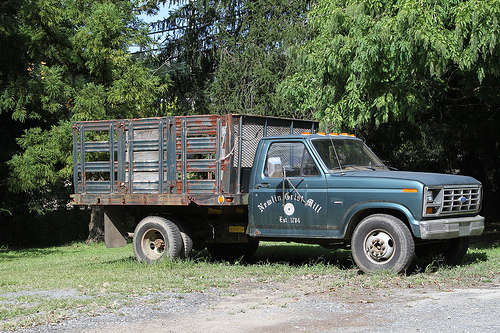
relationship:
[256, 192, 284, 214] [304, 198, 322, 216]
newlin grist mill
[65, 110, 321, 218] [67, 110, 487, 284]
bed of truck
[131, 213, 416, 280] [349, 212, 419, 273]
tires nearly bald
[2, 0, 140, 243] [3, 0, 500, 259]
tree in background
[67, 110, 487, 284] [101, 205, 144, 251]
truck mud flaps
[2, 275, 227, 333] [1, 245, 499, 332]
gravel in foreground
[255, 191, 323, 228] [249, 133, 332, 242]
letters on door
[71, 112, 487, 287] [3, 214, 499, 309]
parked in grass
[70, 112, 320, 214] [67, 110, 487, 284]
back of truck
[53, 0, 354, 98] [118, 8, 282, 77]
covered electrical lines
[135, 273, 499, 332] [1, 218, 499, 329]
dirt covering ground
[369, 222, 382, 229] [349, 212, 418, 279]
black old tire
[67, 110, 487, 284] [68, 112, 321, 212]
truck with trailer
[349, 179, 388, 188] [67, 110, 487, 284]
green pickup truck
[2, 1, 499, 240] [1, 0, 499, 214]
trees with leaves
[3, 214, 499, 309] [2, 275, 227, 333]
grass and gravel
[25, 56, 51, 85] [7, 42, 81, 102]
flowers on branch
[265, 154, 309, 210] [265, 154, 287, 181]
side view mirror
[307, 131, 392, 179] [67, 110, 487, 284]
windshield of truck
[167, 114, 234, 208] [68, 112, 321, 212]
rusty grid trailer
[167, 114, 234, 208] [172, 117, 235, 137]
rusty trailer railing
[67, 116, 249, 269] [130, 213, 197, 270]
rear two tires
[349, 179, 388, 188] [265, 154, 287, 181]
green truck mirror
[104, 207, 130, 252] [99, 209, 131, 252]
faded black mudflap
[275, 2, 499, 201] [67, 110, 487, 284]
tree overlooking truck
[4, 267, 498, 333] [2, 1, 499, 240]
road amid trees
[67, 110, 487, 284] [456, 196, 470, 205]
truck grille logo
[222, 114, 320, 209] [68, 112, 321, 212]
front of trailer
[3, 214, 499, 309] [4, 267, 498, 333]
grass along road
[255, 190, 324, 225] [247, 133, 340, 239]
lettering on side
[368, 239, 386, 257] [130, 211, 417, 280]
bolts on wheels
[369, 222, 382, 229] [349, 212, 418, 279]
black rubber tire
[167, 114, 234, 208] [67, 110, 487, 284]
rusty green truck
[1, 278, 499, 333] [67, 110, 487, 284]
area near truck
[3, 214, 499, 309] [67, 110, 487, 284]
grass around truck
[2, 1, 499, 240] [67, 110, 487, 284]
trees over vehical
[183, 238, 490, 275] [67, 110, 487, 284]
shadow under truck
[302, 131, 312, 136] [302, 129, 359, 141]
yellow caution light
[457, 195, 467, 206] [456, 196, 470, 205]
blue company logo